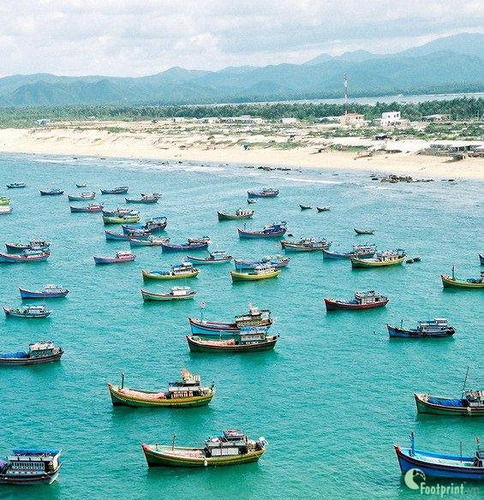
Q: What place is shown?
A: It is an ocean.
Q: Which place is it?
A: It is an ocean.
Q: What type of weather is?
A: It is cloudy.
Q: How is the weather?
A: It is cloudy.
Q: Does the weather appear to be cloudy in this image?
A: Yes, it is cloudy.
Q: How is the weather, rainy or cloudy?
A: It is cloudy.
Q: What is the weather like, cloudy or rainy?
A: It is cloudy.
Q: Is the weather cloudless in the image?
A: No, it is cloudy.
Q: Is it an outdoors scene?
A: Yes, it is outdoors.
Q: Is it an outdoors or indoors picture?
A: It is outdoors.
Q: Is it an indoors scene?
A: No, it is outdoors.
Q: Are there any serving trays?
A: No, there are no serving trays.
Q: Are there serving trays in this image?
A: No, there are no serving trays.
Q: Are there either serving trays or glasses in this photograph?
A: No, there are no serving trays or glasses.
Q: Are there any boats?
A: Yes, there is a boat.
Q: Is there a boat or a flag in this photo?
A: Yes, there is a boat.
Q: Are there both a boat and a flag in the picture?
A: No, there is a boat but no flags.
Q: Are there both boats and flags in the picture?
A: No, there is a boat but no flags.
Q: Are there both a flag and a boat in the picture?
A: No, there is a boat but no flags.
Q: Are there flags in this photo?
A: No, there are no flags.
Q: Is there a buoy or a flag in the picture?
A: No, there are no flags or buoys.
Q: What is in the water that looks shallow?
A: The boat is in the water.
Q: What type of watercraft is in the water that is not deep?
A: The watercraft is a boat.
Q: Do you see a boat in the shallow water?
A: Yes, there is a boat in the water.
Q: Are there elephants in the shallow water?
A: No, there is a boat in the water.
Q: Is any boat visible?
A: Yes, there is a boat.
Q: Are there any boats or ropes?
A: Yes, there is a boat.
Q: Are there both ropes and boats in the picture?
A: No, there is a boat but no ropes.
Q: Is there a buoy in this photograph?
A: No, there are no buoys.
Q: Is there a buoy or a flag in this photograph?
A: No, there are no buoys or flags.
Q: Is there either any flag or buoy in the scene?
A: No, there are no buoys or flags.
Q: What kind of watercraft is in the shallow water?
A: The watercraft is a boat.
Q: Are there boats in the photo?
A: Yes, there is a boat.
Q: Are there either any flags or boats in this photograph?
A: Yes, there is a boat.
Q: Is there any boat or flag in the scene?
A: Yes, there is a boat.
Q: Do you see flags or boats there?
A: Yes, there is a boat.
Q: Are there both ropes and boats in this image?
A: No, there is a boat but no ropes.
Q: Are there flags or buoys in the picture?
A: No, there are no buoys or flags.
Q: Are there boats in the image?
A: Yes, there is a boat.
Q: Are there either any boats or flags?
A: Yes, there is a boat.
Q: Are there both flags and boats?
A: No, there is a boat but no flags.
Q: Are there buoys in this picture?
A: No, there are no buoys.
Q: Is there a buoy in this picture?
A: No, there are no buoys.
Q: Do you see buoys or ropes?
A: No, there are no buoys or ropes.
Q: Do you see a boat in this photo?
A: Yes, there is a boat.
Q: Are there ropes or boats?
A: Yes, there is a boat.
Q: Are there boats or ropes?
A: Yes, there is a boat.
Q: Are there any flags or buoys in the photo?
A: No, there are no buoys or flags.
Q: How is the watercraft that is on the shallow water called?
A: The watercraft is a boat.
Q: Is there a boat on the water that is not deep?
A: Yes, there is a boat on the water.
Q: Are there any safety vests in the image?
A: No, there are no safety vests.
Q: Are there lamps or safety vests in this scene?
A: No, there are no safety vests or lamps.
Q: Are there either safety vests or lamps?
A: No, there are no safety vests or lamps.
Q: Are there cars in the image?
A: No, there are no cars.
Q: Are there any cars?
A: No, there are no cars.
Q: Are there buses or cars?
A: No, there are no cars or buses.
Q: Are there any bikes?
A: No, there are no bikes.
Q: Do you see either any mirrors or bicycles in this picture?
A: No, there are no bicycles or mirrors.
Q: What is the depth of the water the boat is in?
A: The water is shallow.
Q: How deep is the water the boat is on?
A: The water is shallow.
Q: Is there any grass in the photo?
A: Yes, there is grass.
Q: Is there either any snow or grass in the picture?
A: Yes, there is grass.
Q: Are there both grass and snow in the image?
A: No, there is grass but no snow.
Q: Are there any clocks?
A: No, there are no clocks.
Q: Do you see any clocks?
A: No, there are no clocks.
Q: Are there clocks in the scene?
A: No, there are no clocks.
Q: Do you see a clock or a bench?
A: No, there are no clocks or benches.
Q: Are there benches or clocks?
A: No, there are no clocks or benches.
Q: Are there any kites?
A: No, there are no kites.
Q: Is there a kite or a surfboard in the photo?
A: No, there are no kites or surfboards.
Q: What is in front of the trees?
A: The beach is in front of the trees.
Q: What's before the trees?
A: The beach is in front of the trees.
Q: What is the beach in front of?
A: The beach is in front of the trees.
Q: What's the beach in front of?
A: The beach is in front of the trees.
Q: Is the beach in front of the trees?
A: Yes, the beach is in front of the trees.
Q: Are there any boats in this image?
A: Yes, there is a boat.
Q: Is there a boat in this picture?
A: Yes, there is a boat.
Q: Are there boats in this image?
A: Yes, there is a boat.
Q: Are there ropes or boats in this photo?
A: Yes, there is a boat.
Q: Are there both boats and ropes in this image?
A: No, there is a boat but no ropes.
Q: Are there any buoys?
A: No, there are no buoys.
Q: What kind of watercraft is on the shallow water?
A: The watercraft is a boat.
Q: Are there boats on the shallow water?
A: Yes, there is a boat on the water.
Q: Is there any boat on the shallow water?
A: Yes, there is a boat on the water.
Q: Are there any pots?
A: No, there are no pots.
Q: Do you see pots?
A: No, there are no pots.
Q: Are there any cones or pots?
A: No, there are no pots or cones.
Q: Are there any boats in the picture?
A: Yes, there is a boat.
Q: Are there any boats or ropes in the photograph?
A: Yes, there is a boat.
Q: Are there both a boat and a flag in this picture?
A: No, there is a boat but no flags.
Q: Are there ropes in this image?
A: No, there are no ropes.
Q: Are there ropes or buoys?
A: No, there are no ropes or buoys.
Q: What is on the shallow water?
A: The boat is on the water.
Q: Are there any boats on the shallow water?
A: Yes, there is a boat on the water.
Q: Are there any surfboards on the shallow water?
A: No, there is a boat on the water.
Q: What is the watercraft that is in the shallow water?
A: The watercraft is a boat.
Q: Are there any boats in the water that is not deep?
A: Yes, there is a boat in the water.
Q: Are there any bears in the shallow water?
A: No, there is a boat in the water.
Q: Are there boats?
A: Yes, there is a boat.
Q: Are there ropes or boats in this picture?
A: Yes, there is a boat.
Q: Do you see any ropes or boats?
A: Yes, there is a boat.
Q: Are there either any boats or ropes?
A: Yes, there is a boat.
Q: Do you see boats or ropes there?
A: Yes, there is a boat.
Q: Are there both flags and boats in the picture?
A: No, there is a boat but no flags.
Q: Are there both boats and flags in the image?
A: No, there is a boat but no flags.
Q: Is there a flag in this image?
A: No, there are no flags.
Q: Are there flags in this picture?
A: No, there are no flags.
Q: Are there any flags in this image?
A: No, there are no flags.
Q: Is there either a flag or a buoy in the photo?
A: No, there are no flags or buoys.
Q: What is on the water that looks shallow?
A: The boat is on the water.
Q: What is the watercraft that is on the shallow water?
A: The watercraft is a boat.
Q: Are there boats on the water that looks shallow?
A: Yes, there is a boat on the water.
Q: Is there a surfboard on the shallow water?
A: No, there is a boat on the water.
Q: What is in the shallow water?
A: The boat is in the water.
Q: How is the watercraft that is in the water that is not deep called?
A: The watercraft is a boat.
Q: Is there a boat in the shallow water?
A: Yes, there is a boat in the water.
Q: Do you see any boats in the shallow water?
A: Yes, there is a boat in the water.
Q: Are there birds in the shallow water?
A: No, there is a boat in the water.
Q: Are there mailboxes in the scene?
A: No, there are no mailboxes.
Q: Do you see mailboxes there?
A: No, there are no mailboxes.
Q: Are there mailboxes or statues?
A: No, there are no mailboxes or statues.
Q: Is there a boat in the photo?
A: Yes, there is a boat.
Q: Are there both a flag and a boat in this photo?
A: No, there is a boat but no flags.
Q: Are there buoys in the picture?
A: No, there are no buoys.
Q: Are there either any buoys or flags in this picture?
A: No, there are no buoys or flags.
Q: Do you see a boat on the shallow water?
A: Yes, there is a boat on the water.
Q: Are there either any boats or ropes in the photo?
A: Yes, there is a boat.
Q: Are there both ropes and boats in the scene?
A: No, there is a boat but no ropes.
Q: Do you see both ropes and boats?
A: No, there is a boat but no ropes.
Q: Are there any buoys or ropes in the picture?
A: No, there are no buoys or ropes.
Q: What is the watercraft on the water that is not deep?
A: The watercraft is a boat.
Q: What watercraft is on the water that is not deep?
A: The watercraft is a boat.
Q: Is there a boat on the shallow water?
A: Yes, there is a boat on the water.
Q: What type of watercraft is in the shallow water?
A: The watercraft is a boat.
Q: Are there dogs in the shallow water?
A: No, there is a boat in the water.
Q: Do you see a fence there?
A: No, there are no fences.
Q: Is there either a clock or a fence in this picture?
A: No, there are no fences or clocks.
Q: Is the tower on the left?
A: No, the tower is on the right of the image.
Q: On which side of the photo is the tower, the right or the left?
A: The tower is on the right of the image.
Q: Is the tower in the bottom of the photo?
A: No, the tower is in the top of the image.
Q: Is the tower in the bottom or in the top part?
A: The tower is in the top of the image.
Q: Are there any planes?
A: No, there are no planes.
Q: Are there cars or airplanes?
A: No, there are no airplanes or cars.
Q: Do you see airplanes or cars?
A: No, there are no airplanes or cars.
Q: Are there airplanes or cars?
A: No, there are no airplanes or cars.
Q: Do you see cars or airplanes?
A: No, there are no airplanes or cars.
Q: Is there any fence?
A: No, there are no fences.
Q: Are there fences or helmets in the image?
A: No, there are no fences or helmets.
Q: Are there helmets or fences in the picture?
A: No, there are no fences or helmets.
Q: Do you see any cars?
A: No, there are no cars.